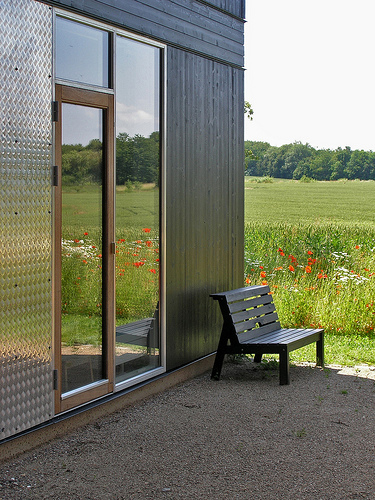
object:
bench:
[210, 282, 327, 381]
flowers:
[259, 270, 268, 278]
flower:
[287, 264, 296, 272]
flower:
[307, 249, 314, 255]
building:
[0, 1, 245, 443]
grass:
[327, 328, 373, 366]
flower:
[292, 288, 300, 294]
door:
[54, 86, 114, 415]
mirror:
[53, 13, 167, 417]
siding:
[50, 76, 66, 419]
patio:
[2, 361, 374, 497]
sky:
[245, 0, 372, 149]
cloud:
[115, 100, 153, 135]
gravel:
[2, 367, 375, 500]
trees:
[344, 146, 374, 180]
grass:
[245, 179, 374, 226]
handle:
[109, 241, 117, 255]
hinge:
[51, 101, 60, 124]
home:
[0, 0, 248, 443]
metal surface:
[2, 3, 55, 442]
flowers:
[278, 247, 283, 253]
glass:
[63, 104, 108, 395]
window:
[52, 17, 115, 88]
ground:
[3, 364, 374, 498]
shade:
[0, 361, 372, 499]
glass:
[111, 29, 164, 396]